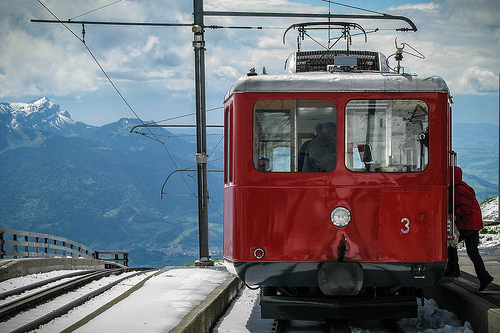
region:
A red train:
[205, 14, 463, 306]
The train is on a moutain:
[187, 2, 469, 302]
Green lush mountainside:
[4, 108, 189, 256]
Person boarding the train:
[438, 146, 491, 290]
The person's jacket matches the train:
[432, 45, 492, 300]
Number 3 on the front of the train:
[379, 202, 430, 245]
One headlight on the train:
[320, 193, 360, 232]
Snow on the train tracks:
[27, 253, 242, 332]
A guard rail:
[2, 218, 125, 266]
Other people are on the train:
[290, 106, 348, 175]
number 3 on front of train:
[395, 205, 413, 236]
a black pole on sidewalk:
[180, 0, 216, 267]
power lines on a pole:
[40, 5, 217, 190]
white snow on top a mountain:
[0, 86, 90, 131]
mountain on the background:
[5, 85, 222, 196]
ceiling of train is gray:
[228, 58, 448, 94]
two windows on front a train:
[243, 90, 439, 186]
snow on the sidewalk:
[20, 248, 226, 326]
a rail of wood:
[3, 223, 132, 266]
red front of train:
[221, 79, 459, 281]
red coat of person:
[445, 165, 485, 232]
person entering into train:
[443, 165, 494, 291]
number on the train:
[397, 217, 411, 236]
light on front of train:
[329, 204, 354, 230]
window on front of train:
[344, 94, 426, 176]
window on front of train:
[251, 87, 340, 175]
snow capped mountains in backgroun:
[4, 98, 75, 128]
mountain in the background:
[103, 114, 173, 141]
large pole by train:
[190, 0, 209, 265]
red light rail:
[231, 42, 451, 292]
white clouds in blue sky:
[70, 48, 112, 79]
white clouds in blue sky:
[57, 91, 104, 111]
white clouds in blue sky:
[130, 45, 165, 70]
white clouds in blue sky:
[30, 52, 81, 84]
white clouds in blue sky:
[122, 103, 157, 141]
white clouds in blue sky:
[107, 2, 167, 66]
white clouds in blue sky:
[221, 31, 258, 59]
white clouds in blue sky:
[442, 26, 473, 70]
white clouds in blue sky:
[71, 36, 171, 114]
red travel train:
[214, 17, 451, 262]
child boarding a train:
[434, 155, 486, 276]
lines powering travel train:
[124, 22, 214, 220]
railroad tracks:
[27, 251, 150, 328]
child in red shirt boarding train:
[440, 148, 491, 275]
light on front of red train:
[316, 208, 366, 223]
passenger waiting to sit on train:
[303, 118, 347, 188]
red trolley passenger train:
[209, 41, 469, 288]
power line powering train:
[179, 14, 239, 262]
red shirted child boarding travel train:
[413, 150, 479, 282]